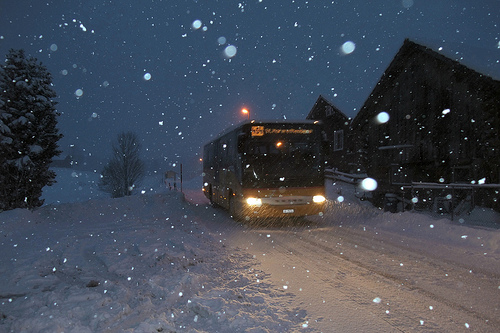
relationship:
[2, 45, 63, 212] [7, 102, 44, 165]
tree covered with snow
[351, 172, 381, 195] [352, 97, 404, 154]
speck of snow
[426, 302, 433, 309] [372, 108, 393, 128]
speck of snow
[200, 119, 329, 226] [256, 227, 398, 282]
bus traveling in snow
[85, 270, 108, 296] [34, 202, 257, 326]
dog poop in snowbank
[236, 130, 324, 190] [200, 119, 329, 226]
windshield of bus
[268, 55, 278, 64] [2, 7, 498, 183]
snow speck in air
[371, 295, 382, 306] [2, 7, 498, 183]
speck in air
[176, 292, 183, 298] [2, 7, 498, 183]
snow speck in air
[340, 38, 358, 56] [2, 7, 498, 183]
snow in air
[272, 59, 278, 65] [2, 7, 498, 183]
snow in air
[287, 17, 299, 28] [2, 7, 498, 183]
snow speck in air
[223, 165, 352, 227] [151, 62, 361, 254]
headlights of bus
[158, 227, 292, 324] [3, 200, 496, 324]
footprints in snow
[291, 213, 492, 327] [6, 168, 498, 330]
tracks in snow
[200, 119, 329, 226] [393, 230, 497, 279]
bus in snow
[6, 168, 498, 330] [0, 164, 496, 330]
snow on ground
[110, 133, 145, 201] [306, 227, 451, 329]
leafless tree on road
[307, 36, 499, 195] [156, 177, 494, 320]
house by roadside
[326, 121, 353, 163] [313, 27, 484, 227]
window in a house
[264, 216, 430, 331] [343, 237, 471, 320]
road covered in snow